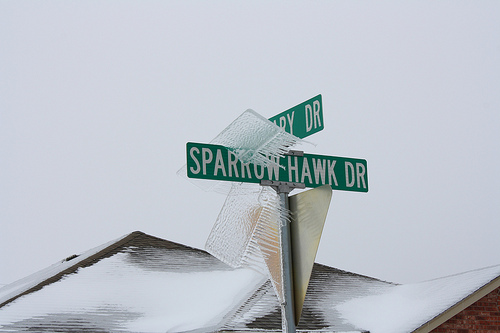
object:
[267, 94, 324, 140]
street signs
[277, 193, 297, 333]
pole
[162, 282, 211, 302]
snow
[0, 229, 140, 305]
roof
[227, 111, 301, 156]
ice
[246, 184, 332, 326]
sign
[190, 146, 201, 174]
s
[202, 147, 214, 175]
p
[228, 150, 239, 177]
r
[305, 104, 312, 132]
white letters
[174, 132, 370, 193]
street sign